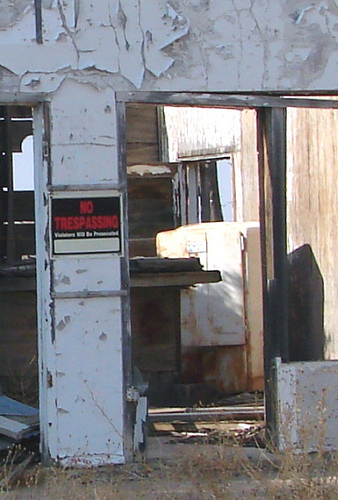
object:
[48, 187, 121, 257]
sign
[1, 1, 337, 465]
paint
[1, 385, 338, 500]
plants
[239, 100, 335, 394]
boards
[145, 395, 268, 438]
boards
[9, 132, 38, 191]
window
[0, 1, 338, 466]
building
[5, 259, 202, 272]
plank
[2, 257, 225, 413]
counter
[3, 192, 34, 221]
planks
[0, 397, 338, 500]
ground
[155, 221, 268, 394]
refrigerator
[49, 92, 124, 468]
wall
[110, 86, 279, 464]
door frame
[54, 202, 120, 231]
no trespassing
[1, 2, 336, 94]
wall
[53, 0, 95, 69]
cracks